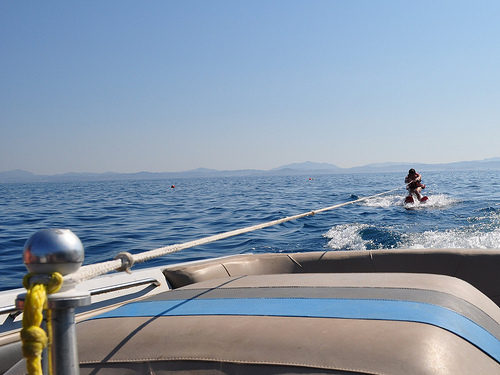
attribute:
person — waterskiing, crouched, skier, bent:
[400, 167, 430, 208]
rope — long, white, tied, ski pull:
[23, 182, 436, 277]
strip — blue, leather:
[83, 297, 499, 362]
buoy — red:
[170, 184, 178, 191]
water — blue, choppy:
[2, 176, 500, 265]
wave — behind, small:
[331, 218, 396, 250]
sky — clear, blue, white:
[3, 2, 500, 161]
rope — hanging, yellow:
[19, 272, 61, 374]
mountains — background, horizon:
[6, 164, 499, 181]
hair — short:
[407, 168, 415, 174]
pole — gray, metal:
[19, 228, 95, 374]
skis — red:
[405, 193, 429, 204]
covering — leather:
[68, 272, 497, 374]